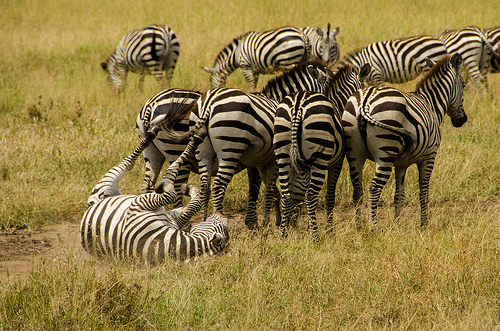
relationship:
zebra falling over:
[75, 157, 243, 266] [78, 140, 224, 268]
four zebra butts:
[146, 84, 414, 166] [129, 86, 410, 164]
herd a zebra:
[76, 26, 496, 263] [75, 157, 243, 266]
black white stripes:
[366, 102, 403, 112] [365, 90, 430, 152]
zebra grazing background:
[106, 20, 182, 90] [0, 0, 377, 80]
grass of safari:
[0, 30, 84, 207] [0, 8, 489, 323]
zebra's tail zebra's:
[163, 98, 216, 144] [158, 84, 217, 144]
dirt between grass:
[0, 215, 75, 295] [0, 30, 84, 207]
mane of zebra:
[412, 53, 458, 91] [75, 157, 243, 266]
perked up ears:
[323, 65, 336, 78] [320, 65, 376, 83]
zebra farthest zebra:
[96, 20, 183, 96] [75, 157, 243, 266]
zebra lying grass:
[75, 157, 243, 266] [0, 30, 84, 207]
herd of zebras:
[76, 26, 496, 263] [0, 8, 489, 323]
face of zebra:
[314, 26, 342, 65] [307, 20, 340, 66]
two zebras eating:
[345, 26, 482, 78] [333, 21, 486, 84]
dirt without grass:
[0, 212, 94, 296] [0, 30, 84, 207]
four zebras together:
[146, 84, 414, 166] [128, 52, 470, 206]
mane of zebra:
[412, 53, 458, 91] [343, 57, 468, 230]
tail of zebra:
[145, 31, 170, 66] [106, 20, 182, 90]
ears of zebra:
[194, 233, 230, 248] [75, 157, 243, 266]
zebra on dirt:
[75, 157, 243, 266] [0, 212, 94, 296]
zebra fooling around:
[75, 157, 243, 266] [70, 116, 252, 259]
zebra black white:
[343, 57, 468, 230] [375, 111, 401, 118]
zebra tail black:
[106, 20, 182, 90] [366, 102, 403, 112]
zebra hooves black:
[75, 157, 243, 266] [366, 102, 403, 112]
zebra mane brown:
[343, 57, 468, 230] [423, 56, 453, 82]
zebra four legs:
[343, 57, 468, 230] [348, 155, 442, 226]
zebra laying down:
[75, 157, 243, 266] [76, 172, 237, 279]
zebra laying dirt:
[75, 157, 243, 266] [0, 215, 75, 295]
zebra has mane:
[343, 57, 468, 230] [412, 53, 458, 91]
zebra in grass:
[96, 20, 183, 96] [0, 30, 84, 207]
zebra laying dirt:
[75, 157, 243, 266] [0, 212, 94, 296]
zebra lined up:
[96, 20, 183, 96] [130, 58, 469, 206]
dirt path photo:
[0, 215, 75, 295] [0, 5, 494, 319]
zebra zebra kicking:
[75, 123, 243, 266] [99, 122, 216, 210]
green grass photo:
[28, 42, 91, 78] [0, 5, 494, 319]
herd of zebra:
[76, 26, 496, 263] [96, 20, 183, 96]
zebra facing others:
[307, 20, 340, 66] [142, 60, 468, 218]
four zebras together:
[146, 84, 414, 166] [128, 52, 474, 244]